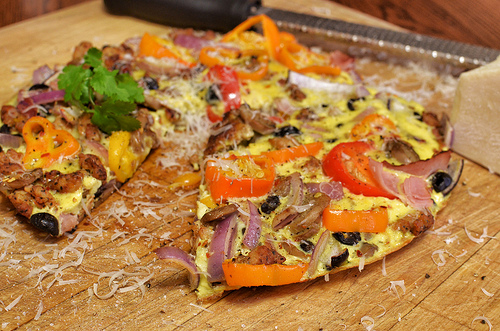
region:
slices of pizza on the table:
[3, 26, 475, 293]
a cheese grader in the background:
[97, 1, 497, 66]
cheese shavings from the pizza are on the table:
[0, 131, 498, 326]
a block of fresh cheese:
[447, 48, 497, 180]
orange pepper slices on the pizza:
[17, 15, 399, 291]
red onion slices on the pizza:
[190, 185, 266, 290]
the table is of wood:
[2, 21, 492, 326]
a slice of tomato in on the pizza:
[315, 128, 402, 201]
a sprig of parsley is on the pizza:
[56, 37, 147, 137]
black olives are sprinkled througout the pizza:
[4, 27, 466, 287]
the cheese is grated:
[85, 179, 169, 296]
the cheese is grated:
[67, 208, 184, 318]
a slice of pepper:
[205, 136, 305, 225]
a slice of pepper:
[174, 120, 306, 200]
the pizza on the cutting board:
[0, 25, 467, 317]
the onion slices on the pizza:
[211, 205, 268, 277]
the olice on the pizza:
[29, 208, 60, 243]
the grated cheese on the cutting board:
[61, 225, 153, 312]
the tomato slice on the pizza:
[320, 133, 391, 200]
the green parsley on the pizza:
[63, 50, 150, 130]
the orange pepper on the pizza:
[22, 116, 134, 181]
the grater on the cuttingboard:
[266, 3, 491, 71]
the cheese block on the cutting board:
[453, 58, 498, 175]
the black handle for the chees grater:
[103, 0, 254, 34]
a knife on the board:
[106, 1, 498, 70]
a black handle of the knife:
[108, 0, 265, 37]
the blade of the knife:
[266, 10, 498, 73]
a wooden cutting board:
[6, 17, 456, 326]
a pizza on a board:
[13, 25, 468, 291]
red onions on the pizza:
[211, 208, 257, 283]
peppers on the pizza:
[207, 145, 294, 200]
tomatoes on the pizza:
[328, 137, 388, 205]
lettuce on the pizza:
[64, 55, 144, 130]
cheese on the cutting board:
[38, 244, 162, 306]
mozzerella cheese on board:
[378, 279, 409, 298]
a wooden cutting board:
[306, 274, 498, 328]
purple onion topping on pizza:
[155, 247, 213, 290]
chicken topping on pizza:
[55, 176, 80, 194]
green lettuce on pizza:
[83, 61, 142, 124]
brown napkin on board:
[459, 68, 498, 165]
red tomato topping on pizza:
[327, 139, 390, 197]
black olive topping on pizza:
[34, 209, 62, 235]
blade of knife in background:
[258, 4, 498, 73]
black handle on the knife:
[87, 4, 259, 23]